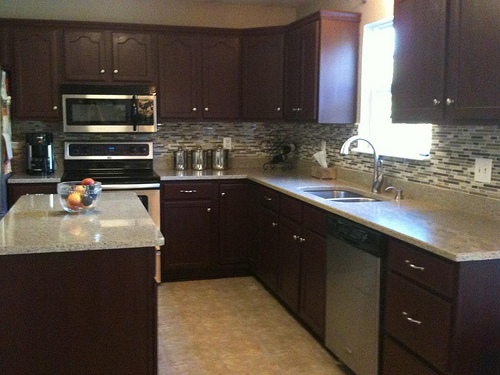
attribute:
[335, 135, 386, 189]
faucet — chrome, gray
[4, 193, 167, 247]
counter — white, brown, tan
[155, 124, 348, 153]
tiles on wall — brown, tan, white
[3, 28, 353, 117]
cabinet — brown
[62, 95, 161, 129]
microwave — black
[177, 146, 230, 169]
metal canisters — chrome, silver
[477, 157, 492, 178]
light switch on wall — white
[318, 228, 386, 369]
dishwasher — stainless steel, silver, black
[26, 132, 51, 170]
coffee maker — black, silver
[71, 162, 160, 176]
top of stove — silver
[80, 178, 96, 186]
apple — red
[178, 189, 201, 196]
handle — metal